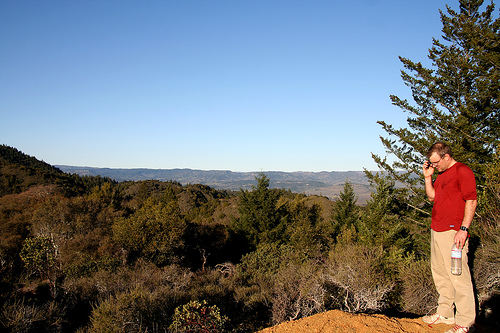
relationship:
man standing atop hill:
[423, 143, 475, 332] [242, 310, 489, 332]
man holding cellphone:
[423, 143, 475, 332] [424, 159, 431, 171]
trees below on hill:
[50, 202, 191, 266] [3, 143, 423, 307]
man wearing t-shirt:
[423, 143, 475, 332] [429, 166, 478, 233]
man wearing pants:
[423, 143, 475, 332] [431, 230, 475, 327]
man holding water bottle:
[423, 143, 475, 332] [451, 244, 464, 277]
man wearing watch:
[423, 143, 475, 332] [461, 223, 470, 232]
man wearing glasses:
[423, 143, 475, 332] [429, 159, 441, 168]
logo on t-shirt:
[440, 178, 455, 192] [429, 166, 478, 233]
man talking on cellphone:
[423, 143, 475, 332] [424, 159, 431, 171]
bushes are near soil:
[272, 228, 421, 318] [289, 316, 368, 332]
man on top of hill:
[423, 143, 475, 332] [242, 310, 489, 332]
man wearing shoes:
[423, 143, 475, 332] [421, 315, 473, 332]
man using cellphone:
[423, 143, 475, 332] [424, 159, 431, 171]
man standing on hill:
[423, 143, 475, 332] [242, 310, 489, 332]